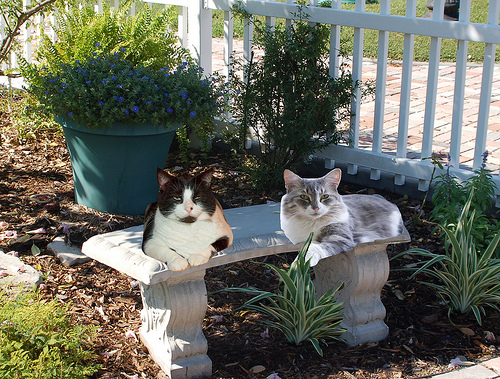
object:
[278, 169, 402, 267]
cat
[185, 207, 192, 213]
nose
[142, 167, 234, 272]
cat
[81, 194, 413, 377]
bench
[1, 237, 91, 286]
stones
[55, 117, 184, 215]
flower pot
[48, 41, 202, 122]
flowers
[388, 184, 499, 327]
monkey grass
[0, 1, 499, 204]
white fence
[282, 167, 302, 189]
ear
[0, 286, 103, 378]
leaves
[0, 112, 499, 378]
soil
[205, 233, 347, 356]
plant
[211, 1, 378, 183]
plant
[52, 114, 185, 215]
pot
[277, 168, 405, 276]
cats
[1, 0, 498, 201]
fence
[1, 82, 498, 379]
garden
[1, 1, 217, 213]
plants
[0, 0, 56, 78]
branch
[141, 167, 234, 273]
fur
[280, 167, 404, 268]
fur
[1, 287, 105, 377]
bush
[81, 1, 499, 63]
grass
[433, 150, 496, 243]
shrub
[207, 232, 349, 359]
foliage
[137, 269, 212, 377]
leg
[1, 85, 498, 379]
dirt